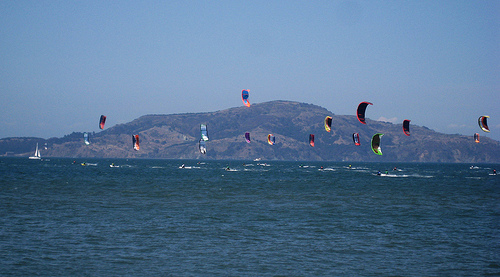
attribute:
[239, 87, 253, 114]
kite — orange, blue, large, red, white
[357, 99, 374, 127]
kite — red, black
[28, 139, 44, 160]
sea boat — white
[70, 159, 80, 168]
person — swimming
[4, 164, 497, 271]
water — blue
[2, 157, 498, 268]
surface — blue, large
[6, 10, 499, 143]
sky — blue, void, cloudless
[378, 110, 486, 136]
clouds — white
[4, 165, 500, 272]
ocean — calm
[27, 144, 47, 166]
boat — sailing, white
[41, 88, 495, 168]
sails — varied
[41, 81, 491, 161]
kites — flying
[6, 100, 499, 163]
land mass — large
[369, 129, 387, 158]
kite — flying, green, black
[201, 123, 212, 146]
kite — blue, white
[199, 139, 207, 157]
kite — blue, white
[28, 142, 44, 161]
sailboat — white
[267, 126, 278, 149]
kite — orange, blue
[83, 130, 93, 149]
kite — blue, white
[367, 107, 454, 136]
cloud — grey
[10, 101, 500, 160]
hill — large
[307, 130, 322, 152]
kite — red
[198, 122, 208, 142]
c-kite — blue